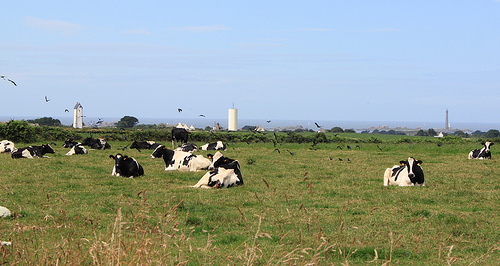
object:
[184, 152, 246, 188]
cattle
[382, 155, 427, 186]
cow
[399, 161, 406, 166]
ear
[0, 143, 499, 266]
grass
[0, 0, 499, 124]
sky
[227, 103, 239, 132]
tower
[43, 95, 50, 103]
bird